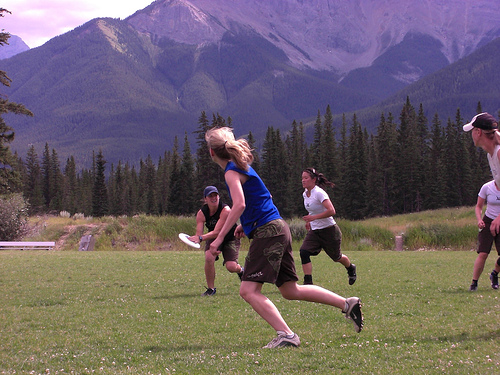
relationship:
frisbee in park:
[172, 219, 217, 258] [111, 82, 487, 367]